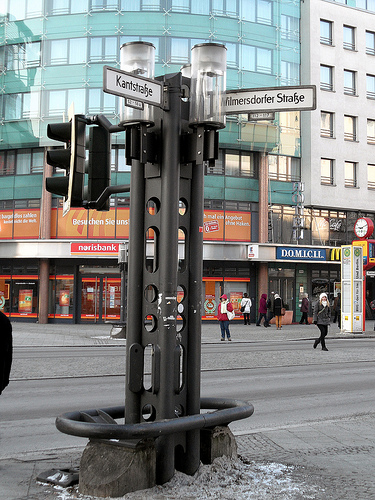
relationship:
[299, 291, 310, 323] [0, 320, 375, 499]
person walking in road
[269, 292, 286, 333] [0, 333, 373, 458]
person walking in street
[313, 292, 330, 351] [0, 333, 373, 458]
person walking in street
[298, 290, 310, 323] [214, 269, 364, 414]
person walking in street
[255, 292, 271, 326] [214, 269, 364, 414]
person walking in street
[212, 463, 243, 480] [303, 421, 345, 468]
snow on sidewalk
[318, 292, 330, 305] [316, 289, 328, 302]
hat on head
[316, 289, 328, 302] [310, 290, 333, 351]
head on woman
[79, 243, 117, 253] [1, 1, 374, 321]
building sign on building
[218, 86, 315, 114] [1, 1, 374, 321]
sign on building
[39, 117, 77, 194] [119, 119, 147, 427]
light on pole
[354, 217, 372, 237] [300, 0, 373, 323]
clock near building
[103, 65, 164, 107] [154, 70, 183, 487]
sign on pole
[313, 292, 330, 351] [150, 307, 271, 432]
person walking on street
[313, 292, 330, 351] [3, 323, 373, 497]
person walking on street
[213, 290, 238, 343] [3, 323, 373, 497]
person walking on street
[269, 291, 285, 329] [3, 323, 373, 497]
person walking on street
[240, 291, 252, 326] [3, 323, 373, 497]
people walking on street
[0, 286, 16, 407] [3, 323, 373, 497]
person walking on street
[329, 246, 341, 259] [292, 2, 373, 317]
logo on building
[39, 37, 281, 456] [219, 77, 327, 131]
metal contraption with street sign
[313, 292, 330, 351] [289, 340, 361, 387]
person walking street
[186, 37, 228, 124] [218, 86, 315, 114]
light next to sign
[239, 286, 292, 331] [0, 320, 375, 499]
people on road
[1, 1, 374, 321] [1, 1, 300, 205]
building made of windows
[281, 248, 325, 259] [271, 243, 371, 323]
building sign over business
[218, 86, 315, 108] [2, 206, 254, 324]
sign over business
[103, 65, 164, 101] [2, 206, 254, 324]
sign over business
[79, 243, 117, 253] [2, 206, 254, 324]
building sign over business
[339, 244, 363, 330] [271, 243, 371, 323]
sign over business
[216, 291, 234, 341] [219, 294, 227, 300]
person wearing hat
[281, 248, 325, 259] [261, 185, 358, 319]
building sign on building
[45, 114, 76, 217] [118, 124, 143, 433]
light on pole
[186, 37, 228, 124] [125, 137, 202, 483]
light on pole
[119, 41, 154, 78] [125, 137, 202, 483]
street light on pole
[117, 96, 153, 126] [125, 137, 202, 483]
street light on pole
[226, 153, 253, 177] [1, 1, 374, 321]
windows on building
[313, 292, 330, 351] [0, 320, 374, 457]
person on road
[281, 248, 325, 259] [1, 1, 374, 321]
building sign on building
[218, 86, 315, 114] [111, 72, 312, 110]
sign in foreign language